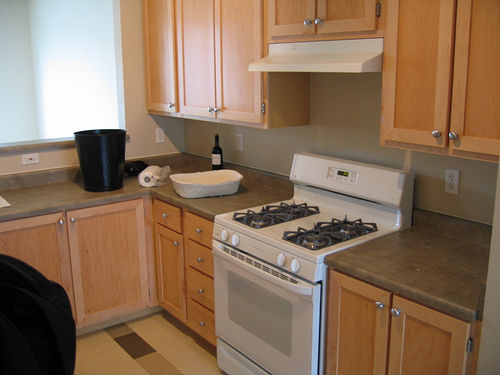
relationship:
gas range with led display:
[210, 150, 419, 373] [333, 170, 349, 180]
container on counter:
[168, 167, 242, 199] [0, 147, 484, 322]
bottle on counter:
[206, 127, 226, 173] [0, 147, 484, 322]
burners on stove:
[229, 186, 383, 264] [201, 155, 421, 280]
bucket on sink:
[73, 127, 128, 192] [3, 149, 188, 230]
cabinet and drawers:
[148, 194, 188, 334] [175, 207, 215, 338]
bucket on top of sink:
[61, 108, 139, 213] [1, 155, 281, 235]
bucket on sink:
[73, 127, 128, 192] [5, 193, 15, 207]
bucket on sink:
[73, 127, 128, 192] [1, 190, 11, 206]